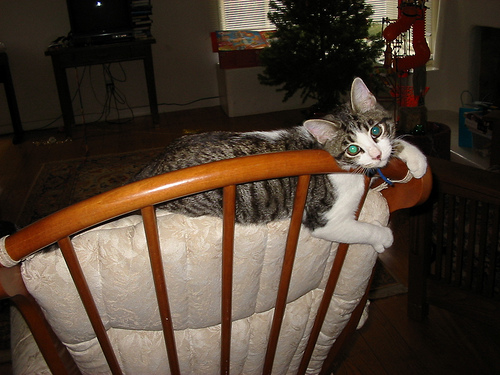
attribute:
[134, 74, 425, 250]
cat — white, grey, looking, tiger cat, laying down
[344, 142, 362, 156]
eye — green, blue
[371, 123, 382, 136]
eye — green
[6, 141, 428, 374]
chair — wooden, made of wood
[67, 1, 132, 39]
tv — in background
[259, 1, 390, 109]
christmas tree — free of decorations, in background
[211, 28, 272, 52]
wrapped gift — colorful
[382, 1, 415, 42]
stocking — red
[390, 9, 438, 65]
stocking — long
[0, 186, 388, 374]
cushion — beige, white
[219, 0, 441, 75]
window — large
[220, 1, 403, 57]
mini blinds — drawn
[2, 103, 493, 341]
carpet — over wooden floor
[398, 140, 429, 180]
paw — white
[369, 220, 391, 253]
paw — white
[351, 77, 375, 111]
ear — alert, sticking up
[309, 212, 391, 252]
front leg — white